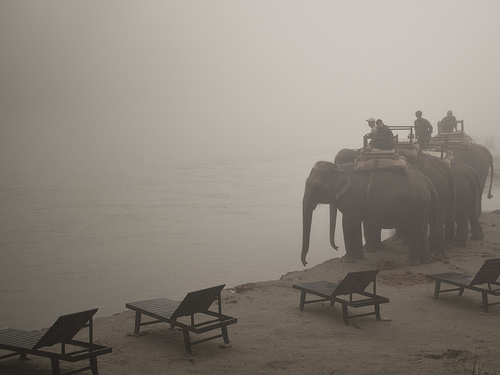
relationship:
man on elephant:
[363, 117, 395, 153] [300, 151, 438, 264]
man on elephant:
[363, 117, 395, 153] [329, 148, 458, 255]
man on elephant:
[407, 109, 433, 144] [425, 143, 485, 242]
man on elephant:
[437, 109, 460, 135] [446, 128, 496, 238]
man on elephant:
[363, 117, 395, 153] [271, 120, 440, 237]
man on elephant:
[413, 109, 433, 144] [300, 151, 438, 264]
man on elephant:
[441, 109, 460, 135] [329, 148, 458, 255]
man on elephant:
[363, 117, 395, 153] [397, 144, 484, 242]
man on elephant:
[363, 118, 375, 141] [412, 139, 492, 217]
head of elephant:
[303, 158, 352, 207] [300, 151, 438, 264]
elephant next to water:
[436, 138, 493, 213] [1, 136, 492, 329]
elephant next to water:
[430, 153, 481, 239] [1, 136, 492, 329]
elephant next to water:
[329, 148, 458, 255] [1, 136, 492, 329]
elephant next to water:
[300, 151, 438, 264] [1, 136, 492, 329]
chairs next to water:
[0, 255, 500, 373] [8, 179, 290, 265]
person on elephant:
[362, 116, 399, 156] [290, 148, 436, 254]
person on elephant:
[405, 105, 440, 159] [300, 151, 438, 264]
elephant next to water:
[300, 151, 438, 264] [6, 6, 498, 330]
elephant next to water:
[371, 127, 484, 225] [6, 6, 498, 330]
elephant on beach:
[300, 151, 438, 264] [1, 207, 498, 374]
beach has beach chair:
[52, 101, 487, 368] [292, 268, 387, 328]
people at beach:
[368, 107, 462, 134] [230, 289, 365, 369]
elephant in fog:
[300, 151, 438, 264] [0, 9, 498, 344]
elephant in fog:
[336, 145, 458, 264] [0, 9, 498, 344]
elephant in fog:
[389, 139, 491, 247] [0, 9, 498, 344]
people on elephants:
[356, 115, 398, 157] [267, 106, 497, 268]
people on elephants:
[405, 102, 436, 144] [267, 106, 497, 268]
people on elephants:
[431, 105, 462, 137] [267, 106, 497, 268]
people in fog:
[356, 115, 398, 157] [23, 27, 283, 249]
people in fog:
[405, 102, 436, 144] [23, 27, 283, 249]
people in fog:
[431, 105, 462, 137] [23, 27, 283, 249]